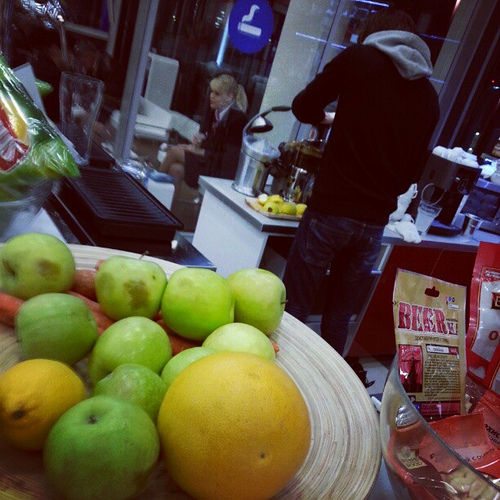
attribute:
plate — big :
[4, 242, 380, 497]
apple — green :
[42, 395, 161, 497]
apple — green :
[96, 364, 168, 422]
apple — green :
[90, 315, 171, 377]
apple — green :
[162, 267, 234, 342]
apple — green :
[95, 255, 167, 321]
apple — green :
[14, 291, 98, 363]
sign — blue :
[227, 0, 276, 51]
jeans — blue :
[282, 206, 387, 359]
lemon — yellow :
[0, 358, 90, 452]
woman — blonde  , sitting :
[159, 74, 251, 187]